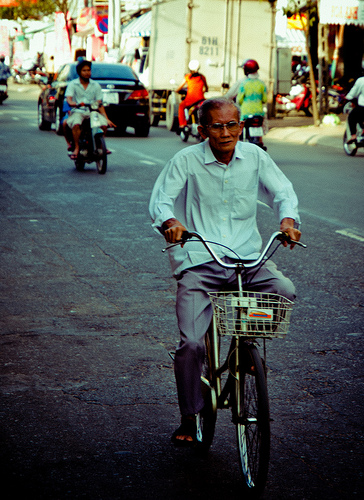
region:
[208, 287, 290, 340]
metal basket on front of bike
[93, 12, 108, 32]
blue and red sign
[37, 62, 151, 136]
black car on the road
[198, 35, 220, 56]
black numbers on the side of the building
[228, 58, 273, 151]
person on motorbike wearing a red helmet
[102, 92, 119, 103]
white license plate on black car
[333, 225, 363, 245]
white line in the road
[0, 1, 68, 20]
green leaves on upper left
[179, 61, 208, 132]
person in bright orange clothing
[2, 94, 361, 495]
road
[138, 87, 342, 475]
an old man on bike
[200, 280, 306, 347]
wire basket on front of bike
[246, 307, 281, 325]
white and red sign on basket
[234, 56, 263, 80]
a red motorcycle helmet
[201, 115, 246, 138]
glasses on man's face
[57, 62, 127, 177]
a man on a scooter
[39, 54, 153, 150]
a black car going the other direction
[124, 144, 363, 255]
white dotted line on road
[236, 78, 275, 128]
back of a green and blue shirt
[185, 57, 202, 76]
a white motorcycle helmet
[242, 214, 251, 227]
part of a shirt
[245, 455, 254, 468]
part of a wheel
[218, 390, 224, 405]
part of a wheel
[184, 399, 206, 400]
part of a trouser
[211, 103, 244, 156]
face of a man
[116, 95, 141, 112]
back of a car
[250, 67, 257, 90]
back of a woman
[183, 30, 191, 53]
side of a truck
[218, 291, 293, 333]
Basket on the bike.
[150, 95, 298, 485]
Older man on the bike.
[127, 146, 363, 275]
White lines on the ground.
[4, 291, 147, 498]
The road is paved.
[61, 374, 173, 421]
Crack in the road.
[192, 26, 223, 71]
Writing on the truck.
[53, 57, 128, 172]
Man on a moped.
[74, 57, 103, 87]
The man is wearing a helmet.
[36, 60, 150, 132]
The car is black.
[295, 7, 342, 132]
Tree on the side of the road.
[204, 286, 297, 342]
basket on front of bicycle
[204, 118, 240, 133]
glasses on mans face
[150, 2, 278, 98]
back of large truck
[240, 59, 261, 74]
red and black helmet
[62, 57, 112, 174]
man riding a motor bike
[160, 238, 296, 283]
brake cables on bicycle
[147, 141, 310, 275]
long sleeve white shirt with buttons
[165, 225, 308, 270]
handle bars on bicycle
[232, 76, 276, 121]
blue and yellow shirt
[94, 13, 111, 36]
red and blue sign